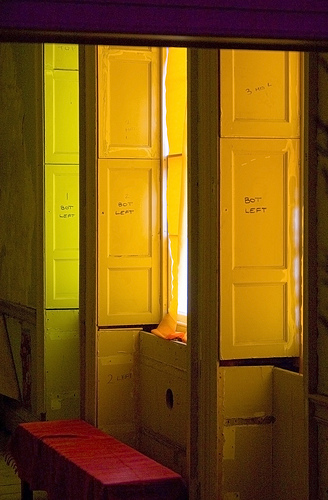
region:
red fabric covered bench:
[3, 416, 182, 499]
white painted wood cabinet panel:
[42, 164, 80, 309]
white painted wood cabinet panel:
[43, 43, 79, 162]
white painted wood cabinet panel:
[95, 45, 160, 159]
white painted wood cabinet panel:
[97, 158, 162, 323]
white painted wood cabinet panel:
[218, 49, 301, 139]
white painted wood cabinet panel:
[217, 137, 301, 358]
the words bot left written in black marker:
[243, 193, 268, 215]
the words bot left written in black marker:
[113, 199, 137, 216]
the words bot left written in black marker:
[58, 204, 76, 220]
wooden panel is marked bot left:
[216, 133, 312, 363]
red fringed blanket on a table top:
[0, 416, 183, 499]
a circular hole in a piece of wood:
[162, 384, 178, 414]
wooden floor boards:
[0, 454, 44, 499]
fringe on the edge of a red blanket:
[2, 445, 24, 482]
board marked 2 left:
[94, 326, 143, 448]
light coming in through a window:
[157, 48, 191, 324]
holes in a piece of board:
[222, 415, 242, 429]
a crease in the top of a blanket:
[39, 428, 99, 442]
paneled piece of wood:
[96, 45, 164, 159]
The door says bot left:
[246, 180, 272, 217]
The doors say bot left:
[33, 156, 286, 257]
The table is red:
[0, 402, 170, 495]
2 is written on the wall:
[96, 360, 118, 389]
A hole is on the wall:
[159, 377, 178, 411]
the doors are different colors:
[42, 46, 299, 344]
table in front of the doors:
[19, 419, 181, 490]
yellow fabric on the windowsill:
[153, 310, 185, 336]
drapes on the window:
[163, 47, 186, 325]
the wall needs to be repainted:
[0, 53, 41, 332]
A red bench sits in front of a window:
[8, 398, 216, 498]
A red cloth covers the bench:
[3, 421, 205, 499]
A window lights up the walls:
[148, 44, 219, 324]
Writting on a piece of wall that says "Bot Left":
[234, 188, 270, 223]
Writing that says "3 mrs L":
[242, 79, 286, 101]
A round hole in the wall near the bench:
[155, 380, 183, 424]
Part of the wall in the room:
[3, 44, 40, 419]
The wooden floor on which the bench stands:
[1, 433, 52, 499]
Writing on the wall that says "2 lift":
[103, 371, 146, 384]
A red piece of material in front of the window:
[137, 303, 202, 345]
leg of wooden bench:
[16, 480, 35, 499]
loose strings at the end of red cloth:
[1, 448, 19, 475]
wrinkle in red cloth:
[38, 432, 85, 441]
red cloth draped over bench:
[6, 417, 184, 499]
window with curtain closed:
[160, 156, 186, 338]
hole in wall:
[164, 387, 175, 412]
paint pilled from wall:
[1, 47, 35, 200]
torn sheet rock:
[222, 412, 274, 427]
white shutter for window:
[96, 159, 162, 323]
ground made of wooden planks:
[2, 474, 17, 499]